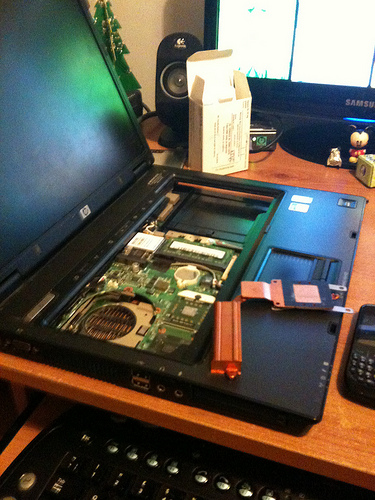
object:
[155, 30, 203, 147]
speaker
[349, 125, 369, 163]
mickey mouse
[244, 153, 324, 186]
desk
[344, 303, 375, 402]
cellphone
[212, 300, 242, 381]
device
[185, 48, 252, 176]
box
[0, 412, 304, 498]
keyboard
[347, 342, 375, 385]
keyboard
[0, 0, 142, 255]
computer screen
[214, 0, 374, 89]
computer monitor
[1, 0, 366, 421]
laptop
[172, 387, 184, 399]
jack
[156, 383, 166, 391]
jack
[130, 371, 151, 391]
jack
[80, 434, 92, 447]
escape key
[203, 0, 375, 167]
computer